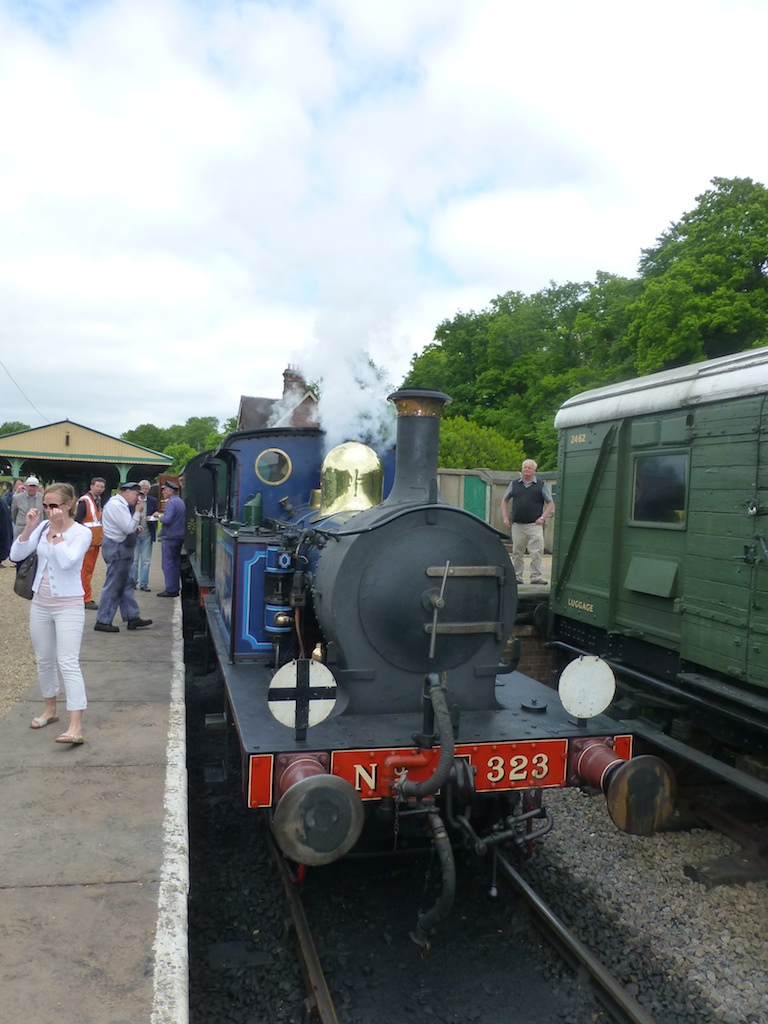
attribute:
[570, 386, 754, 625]
train — small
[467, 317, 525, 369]
tree — large, green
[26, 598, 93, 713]
pants — white, capri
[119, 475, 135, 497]
hat — blue